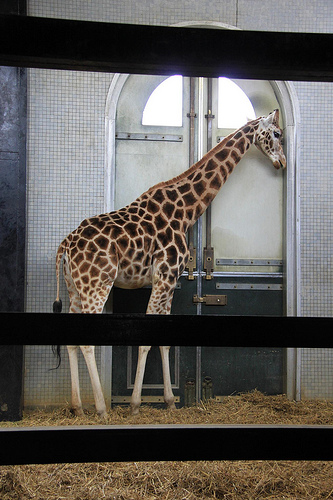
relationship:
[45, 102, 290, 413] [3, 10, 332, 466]
giraffe behind fence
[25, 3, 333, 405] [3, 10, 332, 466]
wall behind fence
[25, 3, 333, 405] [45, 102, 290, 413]
wall behind giraffe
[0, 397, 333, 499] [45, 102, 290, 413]
floor under giraffe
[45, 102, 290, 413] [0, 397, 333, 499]
giraffe on floor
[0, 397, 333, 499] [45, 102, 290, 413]
floor below giraffe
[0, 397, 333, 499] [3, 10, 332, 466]
floor under fence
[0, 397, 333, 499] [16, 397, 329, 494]
floor on floor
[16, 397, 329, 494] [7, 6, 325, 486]
floor of giraffe pen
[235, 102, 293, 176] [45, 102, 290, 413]
head of giraffe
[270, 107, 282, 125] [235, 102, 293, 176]
horn on head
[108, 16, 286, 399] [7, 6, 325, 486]
door in giraffe pen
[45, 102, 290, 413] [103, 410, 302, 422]
giraffe standing in hay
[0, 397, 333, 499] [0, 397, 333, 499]
floor laying on floor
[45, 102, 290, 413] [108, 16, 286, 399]
giraffe standing next to door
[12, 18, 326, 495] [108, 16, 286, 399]
enclosure has door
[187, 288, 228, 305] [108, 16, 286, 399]
bolt on door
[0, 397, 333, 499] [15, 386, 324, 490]
floor covers floor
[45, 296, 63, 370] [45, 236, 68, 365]
tip of tail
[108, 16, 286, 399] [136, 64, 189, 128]
door has window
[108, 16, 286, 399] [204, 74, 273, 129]
door has window